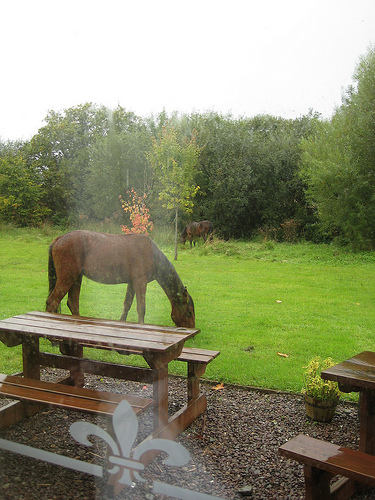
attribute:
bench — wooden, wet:
[274, 435, 366, 479]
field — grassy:
[3, 224, 370, 380]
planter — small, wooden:
[303, 389, 338, 425]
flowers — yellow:
[304, 351, 340, 397]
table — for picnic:
[1, 311, 220, 499]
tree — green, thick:
[298, 42, 369, 248]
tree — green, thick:
[249, 108, 324, 243]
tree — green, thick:
[167, 107, 233, 242]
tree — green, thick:
[1, 141, 51, 225]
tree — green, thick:
[120, 104, 160, 228]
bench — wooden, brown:
[0, 373, 155, 474]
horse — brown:
[33, 226, 196, 337]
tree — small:
[147, 124, 196, 263]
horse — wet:
[45, 227, 196, 345]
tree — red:
[117, 186, 155, 245]